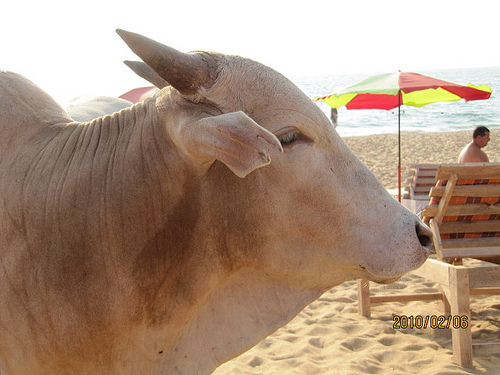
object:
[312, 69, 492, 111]
umbrella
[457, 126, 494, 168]
man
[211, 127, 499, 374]
beach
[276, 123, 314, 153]
eye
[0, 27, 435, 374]
cow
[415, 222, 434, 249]
nostril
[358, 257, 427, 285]
mouth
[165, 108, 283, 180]
ear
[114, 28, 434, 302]
head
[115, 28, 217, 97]
horn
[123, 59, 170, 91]
horn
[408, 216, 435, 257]
nose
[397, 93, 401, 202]
pole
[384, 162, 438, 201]
beach chair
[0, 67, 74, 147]
hump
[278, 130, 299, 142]
eyelashes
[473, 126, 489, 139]
hair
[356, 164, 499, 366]
chair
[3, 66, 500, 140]
water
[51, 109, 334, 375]
neck